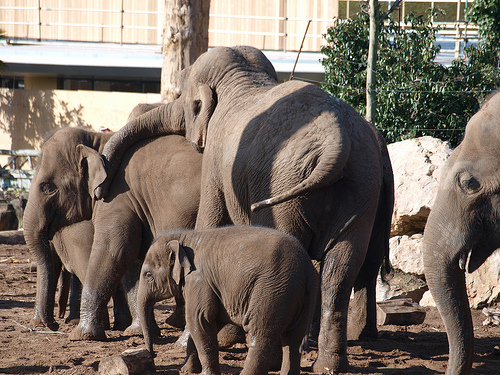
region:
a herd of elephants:
[7, 35, 492, 372]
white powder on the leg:
[72, 286, 109, 331]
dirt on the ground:
[0, 237, 499, 371]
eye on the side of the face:
[452, 163, 491, 201]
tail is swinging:
[236, 162, 355, 216]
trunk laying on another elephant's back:
[83, 87, 208, 206]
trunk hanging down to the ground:
[15, 204, 71, 334]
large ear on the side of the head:
[168, 236, 197, 282]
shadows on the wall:
[1, 89, 110, 166]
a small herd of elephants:
[24, 63, 490, 364]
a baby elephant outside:
[126, 223, 321, 374]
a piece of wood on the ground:
[88, 343, 163, 373]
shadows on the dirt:
[365, 330, 448, 372]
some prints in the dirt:
[66, 339, 111, 374]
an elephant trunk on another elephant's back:
[91, 98, 195, 194]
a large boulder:
[375, 131, 449, 257]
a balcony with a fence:
[1, 0, 453, 85]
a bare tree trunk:
[162, 1, 212, 96]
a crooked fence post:
[358, 4, 383, 126]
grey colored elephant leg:
[278, 319, 305, 373]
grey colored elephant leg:
[183, 293, 221, 373]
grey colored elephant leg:
[311, 226, 366, 372]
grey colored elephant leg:
[71, 218, 129, 340]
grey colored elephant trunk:
[420, 194, 475, 373]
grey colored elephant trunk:
[137, 280, 161, 360]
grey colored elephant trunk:
[93, 105, 177, 202]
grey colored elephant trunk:
[17, 207, 65, 324]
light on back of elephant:
[271, 118, 366, 185]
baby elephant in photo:
[70, 181, 341, 346]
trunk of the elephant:
[126, 290, 164, 347]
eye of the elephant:
[126, 249, 178, 294]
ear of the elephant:
[50, 134, 117, 206]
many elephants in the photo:
[2, 77, 415, 359]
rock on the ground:
[95, 334, 160, 372]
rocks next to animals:
[381, 128, 453, 216]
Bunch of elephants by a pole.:
[268, 178, 325, 215]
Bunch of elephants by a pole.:
[425, 222, 496, 279]